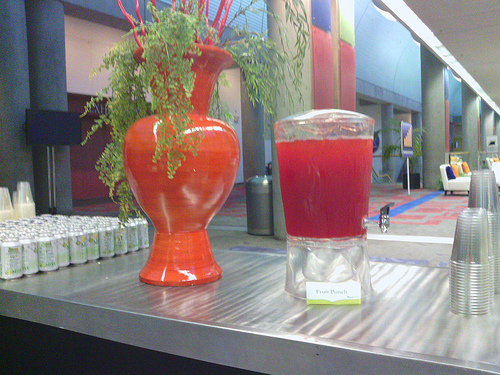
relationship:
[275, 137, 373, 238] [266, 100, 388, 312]
drink in glass container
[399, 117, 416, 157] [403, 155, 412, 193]
sign on pole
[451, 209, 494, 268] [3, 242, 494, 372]
cup on counter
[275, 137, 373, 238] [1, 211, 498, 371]
drink on counter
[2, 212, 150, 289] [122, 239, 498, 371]
cans on counter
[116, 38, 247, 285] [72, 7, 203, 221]
vase with plants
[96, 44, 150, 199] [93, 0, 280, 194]
leaves dangling from plant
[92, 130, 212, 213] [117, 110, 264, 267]
greenery spilling down vase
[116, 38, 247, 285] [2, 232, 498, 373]
vase on table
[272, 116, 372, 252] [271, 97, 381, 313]
drink in glass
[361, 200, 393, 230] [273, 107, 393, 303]
spout on container